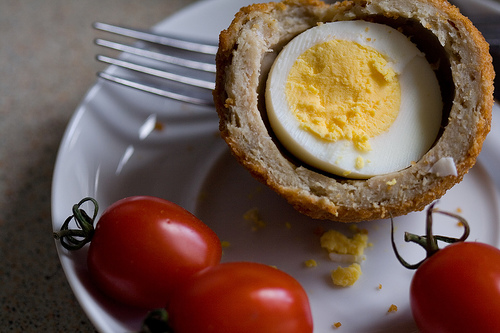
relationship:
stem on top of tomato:
[388, 200, 470, 270] [408, 244, 496, 331]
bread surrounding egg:
[212, 0, 497, 224] [262, 18, 444, 179]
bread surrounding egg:
[416, 0, 494, 170] [262, 18, 444, 179]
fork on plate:
[91, 21, 217, 108] [46, 1, 498, 330]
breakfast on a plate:
[91, 3, 493, 328] [43, 26, 490, 323]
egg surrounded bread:
[262, 18, 444, 179] [211, 1, 498, 224]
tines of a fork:
[97, 71, 207, 103] [94, 19, 262, 124]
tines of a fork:
[93, 35, 217, 70] [94, 19, 262, 124]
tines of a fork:
[91, 19, 217, 53] [94, 19, 262, 124]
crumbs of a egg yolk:
[221, 202, 369, 292] [265, 18, 442, 180]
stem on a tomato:
[387, 201, 469, 269] [411, 241, 499, 332]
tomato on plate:
[133, 258, 313, 331] [46, 1, 498, 330]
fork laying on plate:
[86, 16, 498, 116] [46, 1, 498, 330]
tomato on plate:
[58, 196, 500, 331] [46, 1, 498, 330]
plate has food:
[46, 1, 498, 330] [48, 193, 225, 315]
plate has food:
[46, 1, 498, 330] [134, 259, 314, 331]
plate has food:
[46, 1, 498, 330] [379, 202, 499, 329]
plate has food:
[46, 1, 498, 330] [209, 1, 497, 226]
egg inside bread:
[265, 19, 442, 179] [220, 6, 484, 242]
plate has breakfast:
[46, 1, 498, 330] [50, 0, 500, 333]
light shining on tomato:
[150, 211, 212, 269] [238, 268, 310, 330]